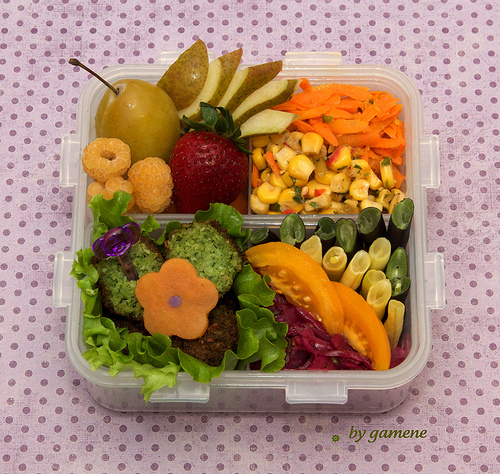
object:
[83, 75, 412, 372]
food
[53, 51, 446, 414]
container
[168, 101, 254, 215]
strawberry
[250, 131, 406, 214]
corn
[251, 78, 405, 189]
carrots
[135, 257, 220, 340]
melon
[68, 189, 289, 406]
flower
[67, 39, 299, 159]
pear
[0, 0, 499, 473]
table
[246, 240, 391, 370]
tomato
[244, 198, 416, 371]
beets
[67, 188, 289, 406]
lettuce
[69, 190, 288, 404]
vegetables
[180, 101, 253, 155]
stem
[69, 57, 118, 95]
stem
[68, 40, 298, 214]
fruit